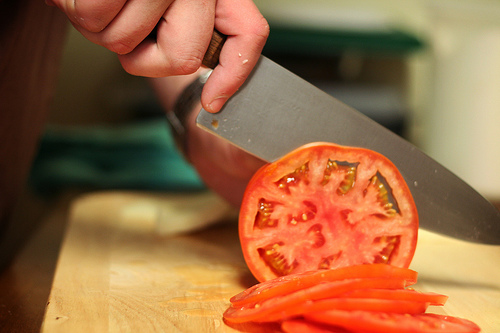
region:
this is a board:
[88, 228, 183, 299]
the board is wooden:
[71, 243, 169, 310]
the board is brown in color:
[81, 242, 137, 291]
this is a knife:
[213, 57, 498, 226]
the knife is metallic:
[261, 82, 303, 131]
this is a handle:
[209, 33, 224, 58]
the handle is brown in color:
[210, 31, 215, 40]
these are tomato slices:
[251, 153, 443, 328]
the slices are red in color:
[312, 291, 361, 321]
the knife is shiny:
[233, 93, 277, 110]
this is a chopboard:
[83, 235, 151, 275]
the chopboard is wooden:
[81, 243, 173, 297]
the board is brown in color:
[84, 235, 195, 305]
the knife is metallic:
[254, 105, 279, 124]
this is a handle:
[213, 37, 220, 47]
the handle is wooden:
[211, 33, 219, 47]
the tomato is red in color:
[260, 308, 276, 317]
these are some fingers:
[116, 10, 233, 56]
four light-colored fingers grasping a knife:
[45, 0, 283, 131]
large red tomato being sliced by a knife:
[218, 136, 497, 329]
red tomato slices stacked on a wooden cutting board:
[213, 263, 492, 331]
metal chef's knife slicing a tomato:
[176, 72, 498, 218]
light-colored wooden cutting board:
[24, 167, 203, 331]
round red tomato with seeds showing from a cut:
[235, 132, 432, 297]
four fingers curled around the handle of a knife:
[60, 2, 242, 114]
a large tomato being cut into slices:
[212, 126, 491, 329]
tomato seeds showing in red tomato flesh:
[359, 168, 408, 221]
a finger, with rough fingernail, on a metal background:
[192, 78, 245, 124]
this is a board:
[126, 253, 168, 293]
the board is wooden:
[98, 230, 156, 292]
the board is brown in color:
[128, 256, 199, 306]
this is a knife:
[257, 73, 293, 120]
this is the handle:
[212, 33, 224, 45]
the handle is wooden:
[209, 38, 222, 52]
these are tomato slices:
[256, 243, 407, 303]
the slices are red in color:
[288, 254, 376, 304]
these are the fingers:
[96, 4, 254, 55]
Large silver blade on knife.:
[221, 49, 488, 254]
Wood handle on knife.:
[192, 30, 241, 72]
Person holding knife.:
[161, 23, 280, 127]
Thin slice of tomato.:
[263, 252, 398, 275]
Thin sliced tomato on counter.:
[285, 282, 356, 294]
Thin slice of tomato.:
[381, 285, 449, 305]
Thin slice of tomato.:
[333, 292, 397, 315]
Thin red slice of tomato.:
[337, 305, 473, 330]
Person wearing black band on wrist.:
[151, 80, 201, 159]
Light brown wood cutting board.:
[101, 199, 152, 323]